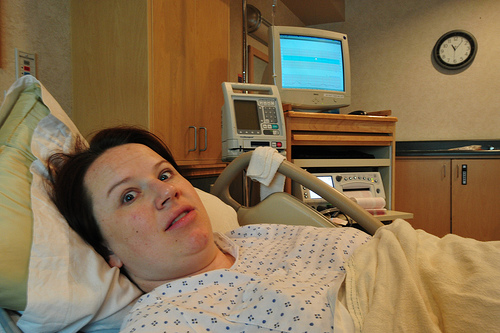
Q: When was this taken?
A: During the day.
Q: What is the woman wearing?
A: A hospital gown.